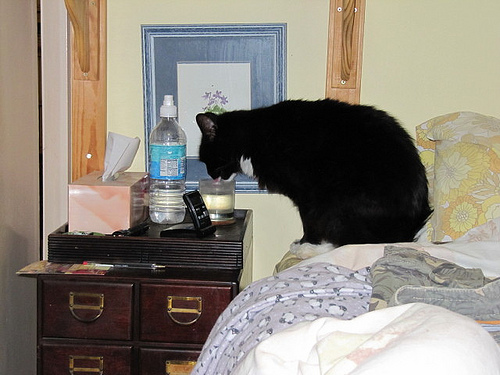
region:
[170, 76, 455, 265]
the cat is on the bed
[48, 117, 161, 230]
a box of tissues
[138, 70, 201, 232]
a bottle of water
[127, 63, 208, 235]
the bottle is plastic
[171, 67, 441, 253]
the cat is black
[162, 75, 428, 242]
the cat has a white patch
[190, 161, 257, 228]
a glass of water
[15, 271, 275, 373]
these are wooden drawers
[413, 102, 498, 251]
this pillowcase has a floral print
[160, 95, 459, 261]
the cat is drinking the water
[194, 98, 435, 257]
black cat with white paws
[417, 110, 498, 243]
yellow and orange pillow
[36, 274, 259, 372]
small wooden night table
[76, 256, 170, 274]
black pen on table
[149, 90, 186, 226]
water bottle with blue label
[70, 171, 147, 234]
orange tissue box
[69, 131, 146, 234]
tissue sticking out of tissue box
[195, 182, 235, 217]
white glass candle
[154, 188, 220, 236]
black folding alarm clock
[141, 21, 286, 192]
purple flower paiting framed in blue frame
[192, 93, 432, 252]
The cat is black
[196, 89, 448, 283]
The cat is sitting on the bed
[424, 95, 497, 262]
The pillow cover is yellow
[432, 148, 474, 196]
The pillow cover has flowers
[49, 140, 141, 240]
The tissue box is pink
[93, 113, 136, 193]
The tissues are white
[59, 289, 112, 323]
The drawer pull is gold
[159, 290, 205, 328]
The drawer pull is gold.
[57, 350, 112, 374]
The drawer pull is gold.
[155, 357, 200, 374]
The drawer pull is gold.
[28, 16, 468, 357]
cat sitting on a bed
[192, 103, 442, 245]
cat drinking out of a glass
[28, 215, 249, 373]
side tables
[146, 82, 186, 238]
water bottle on the end table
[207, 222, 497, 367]
sheets on the bed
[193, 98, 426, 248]
black cat on the bed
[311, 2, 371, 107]
wooden brackets for shelves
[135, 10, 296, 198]
picture frame above the side table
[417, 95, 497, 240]
pillow on the bed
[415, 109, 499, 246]
70s flower print pillow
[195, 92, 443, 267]
a black and white cat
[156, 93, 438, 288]
a cat drinking from it's owner's glass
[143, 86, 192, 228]
plastic bottle of water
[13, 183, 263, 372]
a bedside table made of wood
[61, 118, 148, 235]
a box of kleenex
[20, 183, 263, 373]
an alarm clock on a nightstand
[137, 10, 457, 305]
a cat having a drink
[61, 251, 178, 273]
a ballpoint pen on a wooden platform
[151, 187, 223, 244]
an electronic digital alarm clock